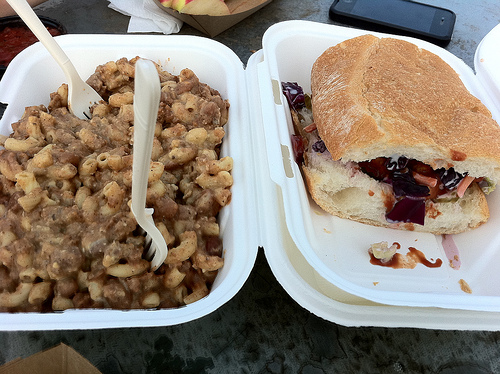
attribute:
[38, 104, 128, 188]
piece — macaroni 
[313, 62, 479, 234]
sandwich — piece 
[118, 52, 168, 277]
fork — white, plastic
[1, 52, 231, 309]
macoroni — piece 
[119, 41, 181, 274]
fork — plastic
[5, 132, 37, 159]
macoroni — piece 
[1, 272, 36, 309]
macaroni piece — small, cooked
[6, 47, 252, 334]
macaroni — cooked, small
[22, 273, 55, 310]
macoroni — piece 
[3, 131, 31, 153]
macaroni — small, cooked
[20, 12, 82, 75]
fork — plastic, white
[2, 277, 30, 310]
macoroni — piece 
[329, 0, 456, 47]
smartphone — black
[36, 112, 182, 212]
macaroni — small, cooked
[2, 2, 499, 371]
tabletop — marble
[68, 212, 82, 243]
maccaroni — piece 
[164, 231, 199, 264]
macaroni — small, cooked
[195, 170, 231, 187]
macaroni — cooked, small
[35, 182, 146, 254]
macaroni — small, cooked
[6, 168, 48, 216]
macaroni — small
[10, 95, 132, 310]
macoroni — piece 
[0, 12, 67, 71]
dish — black, plastic